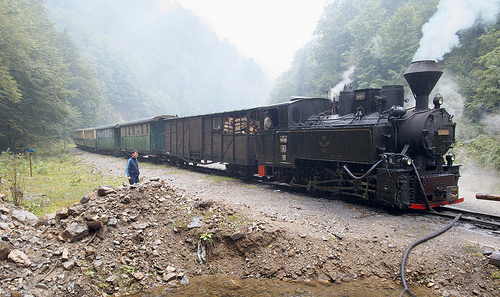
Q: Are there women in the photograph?
A: No, there are no women.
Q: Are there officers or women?
A: No, there are no women or officers.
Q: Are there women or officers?
A: No, there are no women or officers.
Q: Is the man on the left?
A: Yes, the man is on the left of the image.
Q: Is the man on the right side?
A: No, the man is on the left of the image.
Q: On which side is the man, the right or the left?
A: The man is on the left of the image.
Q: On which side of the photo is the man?
A: The man is on the left of the image.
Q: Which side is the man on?
A: The man is on the left of the image.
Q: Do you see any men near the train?
A: Yes, there is a man near the train.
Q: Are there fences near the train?
A: No, there is a man near the train.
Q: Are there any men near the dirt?
A: Yes, there is a man near the dirt.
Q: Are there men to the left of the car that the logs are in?
A: Yes, there is a man to the left of the car.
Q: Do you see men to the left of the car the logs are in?
A: Yes, there is a man to the left of the car.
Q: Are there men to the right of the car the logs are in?
A: No, the man is to the left of the car.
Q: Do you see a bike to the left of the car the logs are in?
A: No, there is a man to the left of the car.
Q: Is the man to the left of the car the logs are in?
A: Yes, the man is to the left of the car.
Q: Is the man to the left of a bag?
A: No, the man is to the left of the car.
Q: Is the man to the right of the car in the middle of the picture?
A: No, the man is to the left of the car.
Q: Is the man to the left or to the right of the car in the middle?
A: The man is to the left of the car.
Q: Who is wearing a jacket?
A: The man is wearing a jacket.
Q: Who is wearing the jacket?
A: The man is wearing a jacket.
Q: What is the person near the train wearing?
A: The man is wearing a jacket.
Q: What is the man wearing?
A: The man is wearing a jacket.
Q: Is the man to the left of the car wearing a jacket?
A: Yes, the man is wearing a jacket.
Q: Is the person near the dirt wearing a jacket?
A: Yes, the man is wearing a jacket.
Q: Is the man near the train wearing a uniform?
A: No, the man is wearing a jacket.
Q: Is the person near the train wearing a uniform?
A: No, the man is wearing a jacket.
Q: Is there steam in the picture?
A: Yes, there is steam.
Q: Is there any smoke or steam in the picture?
A: Yes, there is steam.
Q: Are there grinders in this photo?
A: No, there are no grinders.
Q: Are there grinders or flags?
A: No, there are no grinders or flags.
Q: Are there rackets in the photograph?
A: No, there are no rackets.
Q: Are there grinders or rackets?
A: No, there are no rackets or grinders.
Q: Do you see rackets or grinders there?
A: No, there are no rackets or grinders.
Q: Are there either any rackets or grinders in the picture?
A: No, there are no rackets or grinders.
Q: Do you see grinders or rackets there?
A: No, there are no rackets or grinders.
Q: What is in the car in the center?
A: The logs are in the car.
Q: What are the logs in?
A: The logs are in the car.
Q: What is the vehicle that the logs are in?
A: The vehicle is a car.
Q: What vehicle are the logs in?
A: The logs are in the car.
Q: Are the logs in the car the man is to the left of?
A: Yes, the logs are in the car.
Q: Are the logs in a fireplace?
A: No, the logs are in the car.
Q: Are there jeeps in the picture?
A: No, there are no jeeps.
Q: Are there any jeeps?
A: No, there are no jeeps.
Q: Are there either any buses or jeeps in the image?
A: No, there are no jeeps or buses.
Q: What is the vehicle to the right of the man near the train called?
A: The vehicle is a car.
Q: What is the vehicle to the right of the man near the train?
A: The vehicle is a car.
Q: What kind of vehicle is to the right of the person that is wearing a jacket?
A: The vehicle is a car.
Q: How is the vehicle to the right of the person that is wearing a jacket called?
A: The vehicle is a car.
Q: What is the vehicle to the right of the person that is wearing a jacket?
A: The vehicle is a car.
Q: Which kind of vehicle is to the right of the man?
A: The vehicle is a car.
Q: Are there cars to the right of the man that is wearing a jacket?
A: Yes, there is a car to the right of the man.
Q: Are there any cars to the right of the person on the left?
A: Yes, there is a car to the right of the man.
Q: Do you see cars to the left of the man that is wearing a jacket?
A: No, the car is to the right of the man.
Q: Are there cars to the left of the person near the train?
A: No, the car is to the right of the man.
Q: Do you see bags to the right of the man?
A: No, there is a car to the right of the man.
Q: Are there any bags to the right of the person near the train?
A: No, there is a car to the right of the man.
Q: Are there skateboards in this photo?
A: No, there are no skateboards.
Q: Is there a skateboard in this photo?
A: No, there are no skateboards.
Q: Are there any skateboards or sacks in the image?
A: No, there are no skateboards or sacks.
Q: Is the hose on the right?
A: Yes, the hose is on the right of the image.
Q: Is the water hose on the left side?
A: No, the water hose is on the right of the image.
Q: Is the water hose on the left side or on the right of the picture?
A: The water hose is on the right of the image.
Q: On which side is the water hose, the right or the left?
A: The water hose is on the right of the image.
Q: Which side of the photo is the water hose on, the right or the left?
A: The water hose is on the right of the image.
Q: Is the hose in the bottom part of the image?
A: Yes, the hose is in the bottom of the image.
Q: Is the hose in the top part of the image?
A: No, the hose is in the bottom of the image.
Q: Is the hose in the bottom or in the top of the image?
A: The hose is in the bottom of the image.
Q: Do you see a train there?
A: Yes, there is a train.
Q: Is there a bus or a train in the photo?
A: Yes, there is a train.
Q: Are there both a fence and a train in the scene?
A: No, there is a train but no fences.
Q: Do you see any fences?
A: No, there are no fences.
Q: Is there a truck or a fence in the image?
A: No, there are no fences or trucks.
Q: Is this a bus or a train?
A: This is a train.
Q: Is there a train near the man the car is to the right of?
A: Yes, there is a train near the man.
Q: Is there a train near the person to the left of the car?
A: Yes, there is a train near the man.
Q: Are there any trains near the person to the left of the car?
A: Yes, there is a train near the man.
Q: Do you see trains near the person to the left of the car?
A: Yes, there is a train near the man.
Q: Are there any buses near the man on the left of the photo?
A: No, there is a train near the man.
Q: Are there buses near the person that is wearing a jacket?
A: No, there is a train near the man.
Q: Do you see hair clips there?
A: No, there are no hair clips.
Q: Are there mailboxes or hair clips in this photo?
A: No, there are no hair clips or mailboxes.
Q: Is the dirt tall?
A: Yes, the dirt is tall.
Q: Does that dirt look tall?
A: Yes, the dirt is tall.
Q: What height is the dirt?
A: The dirt is tall.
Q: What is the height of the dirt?
A: The dirt is tall.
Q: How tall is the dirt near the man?
A: The dirt is tall.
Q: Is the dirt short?
A: No, the dirt is tall.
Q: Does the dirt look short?
A: No, the dirt is tall.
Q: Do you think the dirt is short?
A: No, the dirt is tall.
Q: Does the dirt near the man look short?
A: No, the dirt is tall.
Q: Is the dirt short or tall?
A: The dirt is tall.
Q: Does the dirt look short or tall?
A: The dirt is tall.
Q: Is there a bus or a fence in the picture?
A: No, there are no fences or buses.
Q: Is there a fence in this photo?
A: No, there are no fences.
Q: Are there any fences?
A: No, there are no fences.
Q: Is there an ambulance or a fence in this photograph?
A: No, there are no fences or ambulances.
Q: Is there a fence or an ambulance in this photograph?
A: No, there are no fences or ambulances.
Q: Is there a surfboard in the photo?
A: No, there are no surfboards.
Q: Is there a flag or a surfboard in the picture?
A: No, there are no surfboards or flags.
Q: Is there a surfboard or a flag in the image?
A: No, there are no surfboards or flags.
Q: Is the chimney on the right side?
A: Yes, the chimney is on the right of the image.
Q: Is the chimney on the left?
A: No, the chimney is on the right of the image.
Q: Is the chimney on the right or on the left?
A: The chimney is on the right of the image.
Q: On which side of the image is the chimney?
A: The chimney is on the right of the image.